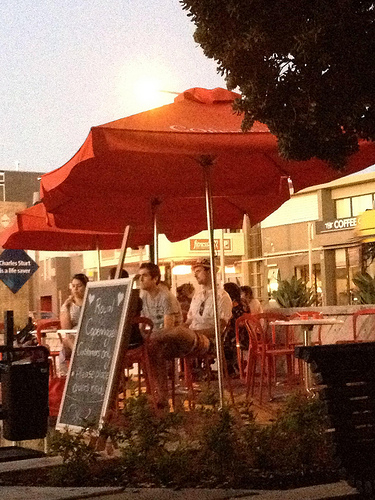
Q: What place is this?
A: It is a restaurant.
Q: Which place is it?
A: It is a restaurant.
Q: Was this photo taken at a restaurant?
A: Yes, it was taken in a restaurant.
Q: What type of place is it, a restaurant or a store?
A: It is a restaurant.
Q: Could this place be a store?
A: No, it is a restaurant.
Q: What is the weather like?
A: It is overcast.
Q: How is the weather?
A: It is overcast.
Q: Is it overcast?
A: Yes, it is overcast.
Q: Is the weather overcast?
A: Yes, it is overcast.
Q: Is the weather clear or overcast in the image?
A: It is overcast.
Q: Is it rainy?
A: No, it is overcast.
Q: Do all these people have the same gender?
A: Yes, all the people are female.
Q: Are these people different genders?
A: No, all the people are female.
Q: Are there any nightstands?
A: No, there are no nightstands.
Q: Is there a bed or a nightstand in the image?
A: No, there are no nightstands or beds.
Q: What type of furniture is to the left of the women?
A: The pieces of furniture are chairs.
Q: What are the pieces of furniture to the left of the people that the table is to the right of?
A: The pieces of furniture are chairs.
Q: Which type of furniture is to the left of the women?
A: The pieces of furniture are chairs.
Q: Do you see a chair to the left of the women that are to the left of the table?
A: Yes, there are chairs to the left of the women.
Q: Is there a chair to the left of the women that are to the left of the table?
A: Yes, there are chairs to the left of the women.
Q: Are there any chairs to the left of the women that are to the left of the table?
A: Yes, there are chairs to the left of the women.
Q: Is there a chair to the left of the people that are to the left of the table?
A: Yes, there are chairs to the left of the women.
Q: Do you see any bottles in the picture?
A: No, there are no bottles.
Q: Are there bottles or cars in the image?
A: No, there are no bottles or cars.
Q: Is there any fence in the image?
A: No, there are no fences.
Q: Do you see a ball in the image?
A: No, there are no balls.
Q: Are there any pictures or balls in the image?
A: No, there are no balls or pictures.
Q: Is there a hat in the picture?
A: Yes, there is a hat.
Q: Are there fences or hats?
A: Yes, there is a hat.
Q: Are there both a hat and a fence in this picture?
A: No, there is a hat but no fences.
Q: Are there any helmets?
A: No, there are no helmets.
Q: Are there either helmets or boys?
A: No, there are no helmets or boys.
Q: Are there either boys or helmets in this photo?
A: No, there are no helmets or boys.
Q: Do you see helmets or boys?
A: No, there are no helmets or boys.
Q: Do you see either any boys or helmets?
A: No, there are no helmets or boys.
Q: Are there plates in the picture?
A: No, there are no plates.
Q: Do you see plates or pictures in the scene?
A: No, there are no plates or pictures.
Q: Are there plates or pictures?
A: No, there are no plates or pictures.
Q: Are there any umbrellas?
A: Yes, there is an umbrella.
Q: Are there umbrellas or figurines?
A: Yes, there is an umbrella.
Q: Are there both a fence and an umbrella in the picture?
A: No, there is an umbrella but no fences.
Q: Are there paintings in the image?
A: No, there are no paintings.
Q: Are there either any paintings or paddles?
A: No, there are no paintings or paddles.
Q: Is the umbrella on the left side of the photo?
A: Yes, the umbrella is on the left of the image.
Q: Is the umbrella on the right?
A: No, the umbrella is on the left of the image.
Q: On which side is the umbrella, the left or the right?
A: The umbrella is on the left of the image.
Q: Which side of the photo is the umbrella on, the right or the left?
A: The umbrella is on the left of the image.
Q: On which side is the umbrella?
A: The umbrella is on the left of the image.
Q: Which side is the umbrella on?
A: The umbrella is on the left of the image.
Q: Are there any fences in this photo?
A: No, there are no fences.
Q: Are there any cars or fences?
A: No, there are no fences or cars.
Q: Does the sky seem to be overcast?
A: Yes, the sky is overcast.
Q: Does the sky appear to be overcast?
A: Yes, the sky is overcast.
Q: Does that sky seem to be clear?
A: No, the sky is overcast.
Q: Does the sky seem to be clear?
A: No, the sky is overcast.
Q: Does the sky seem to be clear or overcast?
A: The sky is overcast.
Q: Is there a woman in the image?
A: Yes, there are women.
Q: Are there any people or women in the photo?
A: Yes, there are women.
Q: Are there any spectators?
A: No, there are no spectators.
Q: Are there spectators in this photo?
A: No, there are no spectators.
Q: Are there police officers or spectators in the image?
A: No, there are no spectators or police officers.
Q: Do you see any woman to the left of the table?
A: Yes, there are women to the left of the table.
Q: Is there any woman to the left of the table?
A: Yes, there are women to the left of the table.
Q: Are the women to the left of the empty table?
A: Yes, the women are to the left of the table.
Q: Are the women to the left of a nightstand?
A: No, the women are to the left of the table.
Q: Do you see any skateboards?
A: No, there are no skateboards.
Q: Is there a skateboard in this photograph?
A: No, there are no skateboards.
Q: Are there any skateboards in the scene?
A: No, there are no skateboards.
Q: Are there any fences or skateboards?
A: No, there are no skateboards or fences.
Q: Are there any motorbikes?
A: No, there are no motorbikes.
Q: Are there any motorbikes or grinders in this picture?
A: No, there are no motorbikes or grinders.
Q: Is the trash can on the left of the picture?
A: Yes, the trash can is on the left of the image.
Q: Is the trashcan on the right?
A: No, the trashcan is on the left of the image.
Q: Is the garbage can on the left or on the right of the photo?
A: The garbage can is on the left of the image.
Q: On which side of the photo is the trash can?
A: The trash can is on the left of the image.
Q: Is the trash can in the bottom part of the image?
A: Yes, the trash can is in the bottom of the image.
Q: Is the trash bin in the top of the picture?
A: No, the trash bin is in the bottom of the image.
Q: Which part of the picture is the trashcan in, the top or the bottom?
A: The trashcan is in the bottom of the image.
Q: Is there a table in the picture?
A: Yes, there is a table.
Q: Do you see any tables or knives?
A: Yes, there is a table.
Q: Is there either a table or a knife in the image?
A: Yes, there is a table.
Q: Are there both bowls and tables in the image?
A: No, there is a table but no bowls.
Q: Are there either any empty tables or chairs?
A: Yes, there is an empty table.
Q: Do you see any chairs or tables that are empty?
A: Yes, the table is empty.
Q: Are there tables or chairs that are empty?
A: Yes, the table is empty.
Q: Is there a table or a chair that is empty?
A: Yes, the table is empty.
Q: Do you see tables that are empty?
A: Yes, there is an empty table.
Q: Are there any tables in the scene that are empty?
A: Yes, there is a table that is empty.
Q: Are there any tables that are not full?
A: Yes, there is a empty table.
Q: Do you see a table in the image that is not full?
A: Yes, there is a empty table.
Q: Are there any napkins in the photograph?
A: No, there are no napkins.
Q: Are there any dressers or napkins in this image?
A: No, there are no napkins or dressers.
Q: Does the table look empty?
A: Yes, the table is empty.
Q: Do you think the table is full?
A: No, the table is empty.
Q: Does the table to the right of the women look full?
A: No, the table is empty.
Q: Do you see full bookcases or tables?
A: No, there is a table but it is empty.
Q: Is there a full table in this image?
A: No, there is a table but it is empty.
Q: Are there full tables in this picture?
A: No, there is a table but it is empty.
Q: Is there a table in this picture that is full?
A: No, there is a table but it is empty.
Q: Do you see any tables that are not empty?
A: No, there is a table but it is empty.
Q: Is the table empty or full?
A: The table is empty.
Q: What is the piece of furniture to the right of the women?
A: The piece of furniture is a table.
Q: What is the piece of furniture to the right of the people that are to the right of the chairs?
A: The piece of furniture is a table.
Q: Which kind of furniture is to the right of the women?
A: The piece of furniture is a table.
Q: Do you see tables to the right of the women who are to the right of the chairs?
A: Yes, there is a table to the right of the women.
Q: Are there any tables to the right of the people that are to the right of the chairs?
A: Yes, there is a table to the right of the women.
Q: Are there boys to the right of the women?
A: No, there is a table to the right of the women.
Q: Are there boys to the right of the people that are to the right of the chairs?
A: No, there is a table to the right of the women.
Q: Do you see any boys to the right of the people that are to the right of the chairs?
A: No, there is a table to the right of the women.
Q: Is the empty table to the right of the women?
A: Yes, the table is to the right of the women.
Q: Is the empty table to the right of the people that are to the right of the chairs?
A: Yes, the table is to the right of the women.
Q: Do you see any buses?
A: No, there are no buses.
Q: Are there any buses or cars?
A: No, there are no buses or cars.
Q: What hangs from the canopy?
A: The sign hangs from the canopy.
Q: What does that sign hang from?
A: The sign hangs from the canopy.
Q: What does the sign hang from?
A: The sign hangs from the canopy.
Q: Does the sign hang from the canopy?
A: Yes, the sign hangs from the canopy.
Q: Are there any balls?
A: No, there are no balls.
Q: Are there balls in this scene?
A: No, there are no balls.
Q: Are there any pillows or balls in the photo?
A: No, there are no balls or pillows.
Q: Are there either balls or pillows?
A: No, there are no balls or pillows.